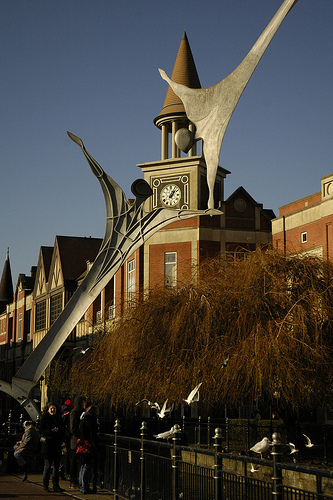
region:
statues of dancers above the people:
[44, 45, 266, 259]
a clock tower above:
[111, 25, 227, 213]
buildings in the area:
[6, 233, 203, 350]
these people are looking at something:
[13, 394, 113, 493]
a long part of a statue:
[12, 226, 124, 396]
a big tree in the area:
[65, 245, 326, 409]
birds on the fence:
[138, 386, 273, 466]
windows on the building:
[114, 255, 185, 311]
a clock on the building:
[155, 178, 188, 214]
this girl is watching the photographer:
[35, 399, 68, 493]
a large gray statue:
[158, 0, 296, 222]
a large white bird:
[249, 434, 273, 460]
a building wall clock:
[159, 183, 183, 206]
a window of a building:
[159, 248, 180, 288]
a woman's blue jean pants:
[41, 456, 61, 485]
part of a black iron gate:
[116, 419, 332, 498]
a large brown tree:
[60, 247, 332, 441]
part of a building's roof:
[56, 234, 99, 275]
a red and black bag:
[73, 436, 93, 456]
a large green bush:
[228, 416, 281, 443]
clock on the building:
[158, 182, 181, 206]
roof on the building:
[37, 233, 110, 300]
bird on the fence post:
[245, 433, 271, 460]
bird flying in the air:
[142, 396, 179, 425]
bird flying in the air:
[179, 380, 207, 409]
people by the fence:
[36, 390, 99, 498]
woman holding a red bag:
[73, 436, 93, 457]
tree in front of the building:
[60, 244, 322, 412]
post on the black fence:
[107, 417, 118, 497]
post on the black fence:
[136, 422, 148, 499]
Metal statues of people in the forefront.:
[0, 1, 291, 414]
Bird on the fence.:
[245, 435, 271, 462]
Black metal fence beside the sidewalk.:
[105, 425, 331, 499]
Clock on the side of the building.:
[159, 183, 182, 206]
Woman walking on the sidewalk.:
[39, 402, 69, 495]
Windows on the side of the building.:
[35, 292, 62, 330]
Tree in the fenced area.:
[74, 250, 329, 455]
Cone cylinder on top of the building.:
[155, 24, 204, 132]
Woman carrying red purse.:
[76, 405, 102, 493]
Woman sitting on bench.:
[9, 418, 41, 484]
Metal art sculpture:
[0, 0, 295, 431]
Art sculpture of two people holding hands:
[0, 0, 296, 423]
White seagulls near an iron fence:
[147, 380, 313, 463]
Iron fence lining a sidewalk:
[75, 417, 332, 498]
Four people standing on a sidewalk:
[34, 395, 98, 494]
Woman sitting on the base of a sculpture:
[10, 419, 39, 482]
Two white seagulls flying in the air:
[153, 378, 202, 419]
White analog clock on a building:
[159, 181, 181, 207]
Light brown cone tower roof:
[153, 29, 216, 134]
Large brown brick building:
[0, 28, 331, 424]